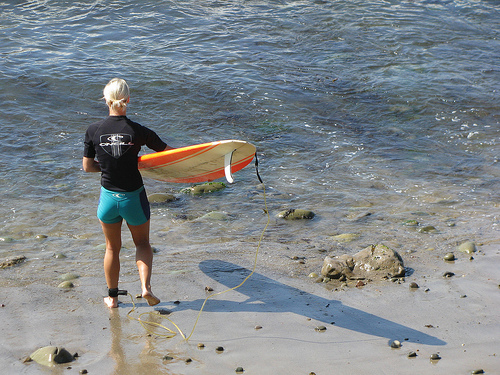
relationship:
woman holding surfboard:
[82, 78, 176, 309] [137, 140, 257, 184]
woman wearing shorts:
[82, 78, 176, 309] [96, 186, 151, 225]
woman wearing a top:
[82, 78, 176, 309] [85, 116, 168, 191]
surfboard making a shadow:
[137, 140, 257, 184] [198, 259, 446, 346]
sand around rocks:
[1, 180, 499, 374] [1, 182, 498, 373]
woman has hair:
[82, 78, 176, 309] [100, 79, 131, 113]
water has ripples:
[1, 1, 498, 285] [0, 0, 500, 291]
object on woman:
[106, 288, 128, 297] [82, 78, 176, 309]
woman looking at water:
[82, 78, 176, 309] [1, 1, 498, 285]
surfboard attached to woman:
[137, 140, 257, 184] [82, 78, 176, 309]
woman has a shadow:
[82, 78, 176, 309] [118, 298, 289, 315]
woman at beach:
[82, 78, 176, 309] [1, 1, 500, 374]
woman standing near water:
[82, 78, 176, 309] [1, 1, 498, 285]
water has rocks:
[1, 1, 498, 285] [1, 182, 498, 373]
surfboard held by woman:
[137, 140, 257, 184] [82, 78, 176, 309]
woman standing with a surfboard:
[82, 78, 176, 309] [137, 140, 257, 184]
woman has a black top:
[82, 78, 176, 309] [85, 116, 168, 191]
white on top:
[99, 132, 134, 160] [85, 116, 168, 191]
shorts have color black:
[96, 186, 151, 225] [139, 187, 151, 220]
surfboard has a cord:
[137, 140, 257, 184] [128, 153, 270, 343]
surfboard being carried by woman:
[137, 140, 257, 184] [82, 78, 176, 309]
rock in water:
[275, 207, 316, 222] [1, 1, 498, 285]